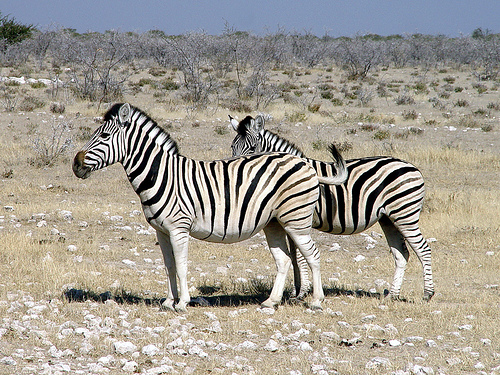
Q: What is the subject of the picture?
A: Two Zebras.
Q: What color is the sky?
A: Blue.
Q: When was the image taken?
A: During the day.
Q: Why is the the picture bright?
A: The sun is shining.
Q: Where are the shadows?
A: Under the zebras.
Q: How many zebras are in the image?
A: Two.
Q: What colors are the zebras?
A: Black and White.